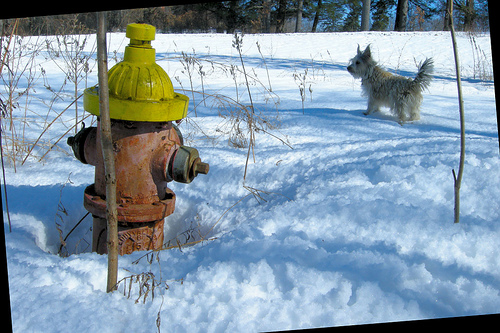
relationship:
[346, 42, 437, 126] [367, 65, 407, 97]
dog has fur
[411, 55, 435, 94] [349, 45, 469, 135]
tail on dog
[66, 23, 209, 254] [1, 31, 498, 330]
fire hydrant surrounded by snow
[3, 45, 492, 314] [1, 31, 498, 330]
shadows on snow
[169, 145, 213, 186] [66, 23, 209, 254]
knob on fire hydrant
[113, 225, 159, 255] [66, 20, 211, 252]
symbol on fire hydrant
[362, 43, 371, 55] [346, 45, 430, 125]
ear of dog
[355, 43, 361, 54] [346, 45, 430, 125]
ear of dog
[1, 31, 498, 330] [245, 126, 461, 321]
snow on ground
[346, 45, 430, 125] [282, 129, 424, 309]
dog standing in snow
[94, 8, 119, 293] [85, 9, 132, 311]
tree has skinny trunk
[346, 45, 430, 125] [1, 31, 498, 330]
dog standing in snow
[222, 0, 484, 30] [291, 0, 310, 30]
sky seen through tree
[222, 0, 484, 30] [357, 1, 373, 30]
sky seen through tree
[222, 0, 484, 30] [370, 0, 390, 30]
sky seen through tree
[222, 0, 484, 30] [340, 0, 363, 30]
sky seen through tree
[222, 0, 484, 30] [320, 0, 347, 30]
sky seen through tree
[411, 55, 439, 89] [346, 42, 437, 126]
tail attached to dog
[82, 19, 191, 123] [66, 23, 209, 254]
top sitting on fire hydrant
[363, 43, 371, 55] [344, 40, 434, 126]
ear standing up on dog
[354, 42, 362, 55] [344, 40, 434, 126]
ear standing up on dog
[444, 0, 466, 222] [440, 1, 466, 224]
trunk belonging to tree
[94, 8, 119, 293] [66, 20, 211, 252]
tree next to fire hydrant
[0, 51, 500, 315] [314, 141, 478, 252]
shadows in snow